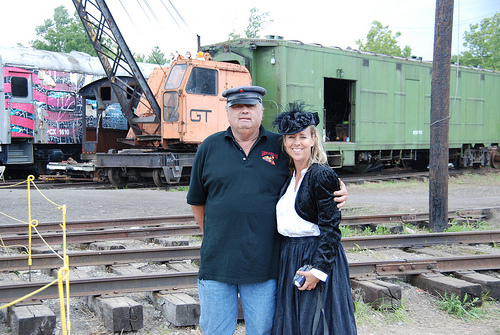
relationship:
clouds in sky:
[0, 1, 474, 60] [110, 2, 498, 56]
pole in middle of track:
[431, 1, 451, 230] [0, 225, 500, 304]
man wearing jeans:
[187, 85, 350, 282] [193, 273, 274, 333]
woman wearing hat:
[269, 106, 361, 331] [273, 87, 330, 139]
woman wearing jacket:
[269, 100, 361, 331] [269, 162, 345, 272]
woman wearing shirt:
[269, 100, 361, 331] [268, 166, 324, 236]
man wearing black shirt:
[187, 85, 350, 282] [187, 123, 280, 282]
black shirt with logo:
[187, 123, 280, 282] [258, 150, 285, 170]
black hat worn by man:
[218, 82, 268, 109] [187, 85, 350, 282]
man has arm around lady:
[187, 85, 350, 282] [277, 110, 340, 237]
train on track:
[121, 36, 500, 151] [358, 213, 453, 293]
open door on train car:
[318, 72, 359, 148] [238, 36, 497, 159]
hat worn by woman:
[272, 102, 319, 135] [269, 100, 361, 331]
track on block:
[2, 225, 499, 287] [410, 272, 482, 307]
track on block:
[2, 225, 499, 287] [347, 277, 401, 312]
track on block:
[2, 225, 499, 287] [147, 290, 198, 327]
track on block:
[2, 225, 499, 287] [80, 292, 141, 333]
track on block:
[2, 225, 499, 287] [10, 298, 57, 333]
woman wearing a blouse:
[269, 100, 361, 331] [275, 167, 322, 235]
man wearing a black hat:
[172, 80, 322, 280] [222, 85, 268, 107]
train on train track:
[238, 35, 498, 158] [342, 164, 476, 184]